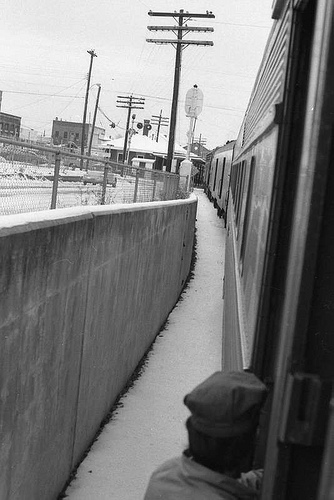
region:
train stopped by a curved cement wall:
[2, 84, 329, 495]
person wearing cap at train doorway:
[141, 363, 269, 493]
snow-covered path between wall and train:
[136, 185, 222, 360]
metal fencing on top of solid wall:
[0, 134, 188, 222]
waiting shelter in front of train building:
[104, 127, 203, 184]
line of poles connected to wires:
[3, 14, 269, 203]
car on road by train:
[0, 156, 164, 210]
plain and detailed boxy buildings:
[0, 107, 104, 165]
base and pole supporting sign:
[174, 76, 200, 197]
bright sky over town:
[2, 4, 275, 148]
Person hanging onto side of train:
[145, 371, 267, 498]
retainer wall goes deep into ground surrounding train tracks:
[1, 132, 196, 497]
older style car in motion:
[81, 159, 119, 185]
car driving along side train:
[84, 156, 118, 185]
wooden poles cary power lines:
[80, 10, 213, 197]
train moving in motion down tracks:
[204, 1, 331, 497]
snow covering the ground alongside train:
[61, 185, 227, 498]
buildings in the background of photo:
[0, 113, 207, 183]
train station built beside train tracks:
[96, 135, 206, 181]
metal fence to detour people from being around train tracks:
[0, 132, 189, 215]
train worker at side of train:
[139, 365, 272, 498]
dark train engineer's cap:
[181, 365, 268, 435]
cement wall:
[2, 190, 196, 497]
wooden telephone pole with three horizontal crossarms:
[146, 8, 212, 173]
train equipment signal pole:
[179, 81, 201, 191]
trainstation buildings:
[93, 117, 202, 186]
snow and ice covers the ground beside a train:
[57, 185, 220, 495]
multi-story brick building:
[49, 116, 105, 171]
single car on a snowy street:
[81, 167, 117, 185]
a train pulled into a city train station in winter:
[1, 4, 332, 497]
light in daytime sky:
[3, 2, 268, 145]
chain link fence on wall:
[0, 136, 193, 494]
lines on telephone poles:
[116, 9, 217, 164]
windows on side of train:
[208, 144, 294, 332]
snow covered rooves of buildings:
[101, 128, 200, 176]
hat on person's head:
[183, 369, 266, 468]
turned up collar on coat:
[149, 451, 255, 498]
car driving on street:
[5, 160, 169, 203]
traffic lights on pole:
[124, 115, 153, 166]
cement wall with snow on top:
[0, 193, 203, 497]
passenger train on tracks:
[201, 47, 327, 364]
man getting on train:
[144, 367, 274, 498]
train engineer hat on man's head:
[181, 365, 270, 437]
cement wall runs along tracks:
[3, 191, 199, 490]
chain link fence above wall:
[0, 136, 194, 213]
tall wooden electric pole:
[146, 7, 215, 169]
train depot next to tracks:
[103, 118, 207, 187]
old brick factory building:
[51, 117, 107, 151]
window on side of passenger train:
[218, 156, 228, 201]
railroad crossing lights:
[132, 119, 152, 131]